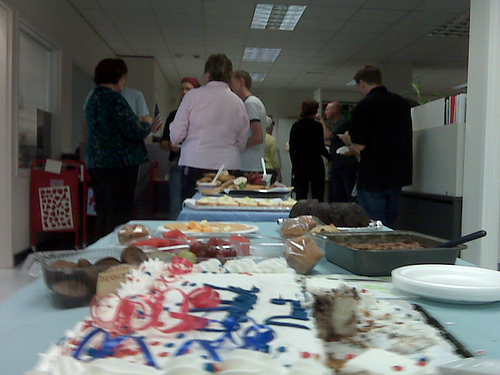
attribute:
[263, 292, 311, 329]
writing — blue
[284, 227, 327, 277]
bag — plastic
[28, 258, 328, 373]
frosting — white